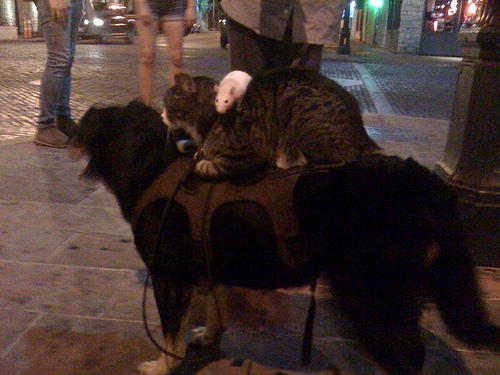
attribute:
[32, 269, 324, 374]
sidewalk — tiled, stone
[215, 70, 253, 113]
mouse — white, small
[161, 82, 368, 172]
cat — brown, sitting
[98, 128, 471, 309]
dog — black, walking, white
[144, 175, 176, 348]
leash — brown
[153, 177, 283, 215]
halter — brown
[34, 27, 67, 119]
jean — blue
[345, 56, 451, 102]
road — brick, red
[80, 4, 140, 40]
car — driving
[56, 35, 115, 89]
street — cobblestone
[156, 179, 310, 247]
vest — brown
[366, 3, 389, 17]
light — green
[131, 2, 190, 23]
shorts — short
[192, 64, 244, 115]
rat — white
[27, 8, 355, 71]
people — watching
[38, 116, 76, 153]
shoe — brown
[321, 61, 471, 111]
roadway — paved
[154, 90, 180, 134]
face — white